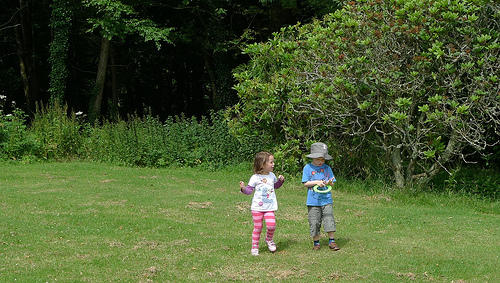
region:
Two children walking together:
[215, 133, 365, 263]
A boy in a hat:
[297, 129, 354, 252]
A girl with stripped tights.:
[230, 141, 291, 274]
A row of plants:
[5, 86, 242, 185]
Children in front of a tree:
[217, 1, 497, 256]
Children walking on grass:
[160, 140, 480, 270]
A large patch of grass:
[5, 168, 238, 268]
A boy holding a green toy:
[294, 133, 366, 265]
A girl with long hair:
[223, 138, 292, 260]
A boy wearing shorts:
[296, 133, 368, 266]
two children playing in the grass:
[235, 135, 353, 260]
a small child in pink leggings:
[236, 144, 289, 260]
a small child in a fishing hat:
[303, 140, 338, 262]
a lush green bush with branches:
[226, 10, 468, 131]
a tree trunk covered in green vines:
[40, 10, 85, 117]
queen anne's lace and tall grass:
[5, 95, 101, 139]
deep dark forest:
[91, 41, 236, 116]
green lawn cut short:
[56, 179, 176, 241]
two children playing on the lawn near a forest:
[153, 65, 406, 266]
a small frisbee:
[308, 176, 343, 202]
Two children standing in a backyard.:
[192, 121, 408, 277]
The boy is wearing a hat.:
[295, 120, 335, 185]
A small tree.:
[245, 0, 490, 175]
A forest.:
[0, 0, 495, 190]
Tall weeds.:
[30, 100, 226, 167]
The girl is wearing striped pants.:
[230, 145, 290, 262]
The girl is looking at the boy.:
[231, 122, 352, 257]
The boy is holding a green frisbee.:
[295, 135, 345, 251]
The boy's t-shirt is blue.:
[295, 140, 345, 260]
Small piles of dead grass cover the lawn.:
[1, 160, 496, 277]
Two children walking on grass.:
[220, 142, 356, 252]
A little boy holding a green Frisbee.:
[305, 170, 370, 240]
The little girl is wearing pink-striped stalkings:
[217, 150, 287, 262]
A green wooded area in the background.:
[35, 12, 382, 187]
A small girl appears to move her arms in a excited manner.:
[221, 140, 291, 245]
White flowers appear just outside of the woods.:
[6, 85, 131, 175]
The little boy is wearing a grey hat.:
[305, 131, 352, 173]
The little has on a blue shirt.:
[292, 171, 345, 212]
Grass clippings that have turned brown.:
[93, 172, 194, 280]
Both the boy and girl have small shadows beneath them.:
[247, 228, 380, 263]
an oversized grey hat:
[299, 133, 336, 159]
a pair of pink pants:
[243, 208, 280, 258]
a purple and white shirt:
[239, 170, 286, 216]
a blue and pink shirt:
[300, 162, 342, 207]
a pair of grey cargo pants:
[304, 197, 341, 239]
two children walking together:
[225, 134, 358, 261]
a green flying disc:
[308, 171, 342, 200]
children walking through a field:
[7, 1, 498, 270]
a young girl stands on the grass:
[218, 129, 294, 266]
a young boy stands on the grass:
[293, 135, 358, 256]